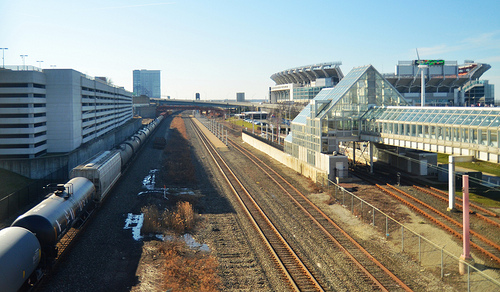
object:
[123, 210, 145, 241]
puddle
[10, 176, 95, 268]
train cart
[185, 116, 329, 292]
track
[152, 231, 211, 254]
puddle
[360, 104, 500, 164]
monorail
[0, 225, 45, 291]
tanker car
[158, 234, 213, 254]
water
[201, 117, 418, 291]
track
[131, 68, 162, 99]
buildling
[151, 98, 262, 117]
bridge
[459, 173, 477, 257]
pole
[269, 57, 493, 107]
stadium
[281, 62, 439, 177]
buildling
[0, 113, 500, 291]
ground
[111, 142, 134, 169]
train car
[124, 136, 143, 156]
train car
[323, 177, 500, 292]
fence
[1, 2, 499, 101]
sky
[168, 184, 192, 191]
puddle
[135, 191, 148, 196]
water